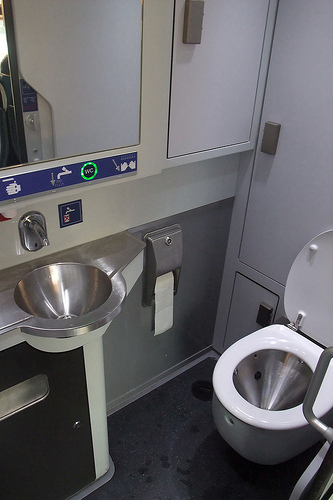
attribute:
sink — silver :
[13, 259, 113, 331]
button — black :
[80, 163, 106, 184]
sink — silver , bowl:
[9, 252, 129, 353]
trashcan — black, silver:
[2, 337, 104, 498]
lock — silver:
[73, 417, 80, 429]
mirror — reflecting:
[3, 0, 140, 172]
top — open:
[225, 344, 310, 410]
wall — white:
[2, 17, 183, 185]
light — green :
[77, 155, 101, 190]